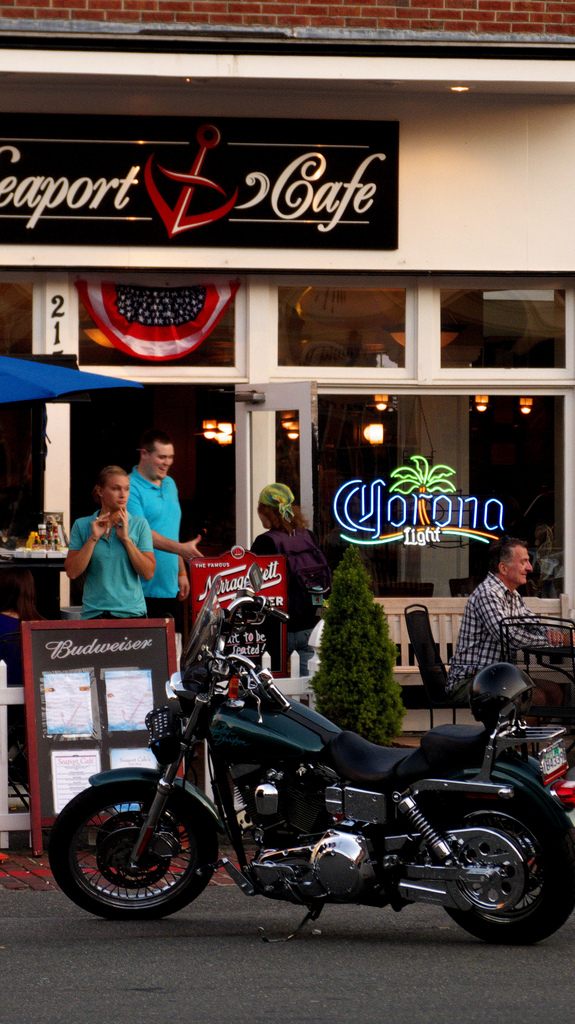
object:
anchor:
[143, 122, 239, 240]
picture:
[0, 6, 572, 1021]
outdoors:
[0, 0, 575, 1022]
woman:
[247, 484, 325, 668]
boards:
[191, 548, 285, 676]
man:
[126, 432, 206, 662]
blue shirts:
[63, 499, 154, 622]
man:
[443, 540, 575, 728]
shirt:
[445, 570, 567, 688]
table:
[501, 610, 571, 699]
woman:
[65, 462, 153, 617]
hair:
[91, 465, 132, 497]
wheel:
[428, 778, 575, 949]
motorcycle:
[41, 574, 575, 948]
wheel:
[46, 761, 221, 930]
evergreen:
[310, 543, 401, 745]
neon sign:
[330, 451, 514, 553]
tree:
[389, 451, 456, 530]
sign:
[0, 110, 397, 249]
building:
[1, 0, 575, 735]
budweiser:
[42, 632, 157, 659]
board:
[19, 614, 186, 853]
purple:
[265, 521, 333, 594]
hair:
[140, 433, 174, 457]